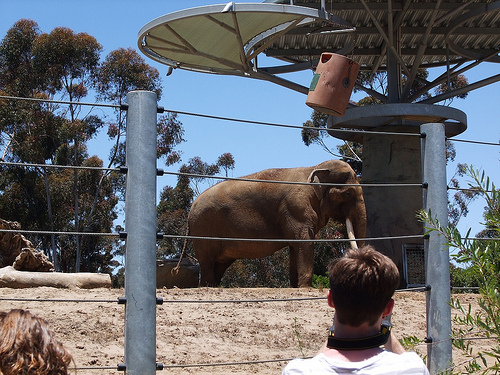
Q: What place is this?
A: It is a zoo.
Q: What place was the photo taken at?
A: It was taken at the zoo.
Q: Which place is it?
A: It is a zoo.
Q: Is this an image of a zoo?
A: Yes, it is showing a zoo.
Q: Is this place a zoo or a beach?
A: It is a zoo.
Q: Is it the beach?
A: No, it is the zoo.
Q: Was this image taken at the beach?
A: No, the picture was taken in the zoo.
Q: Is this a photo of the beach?
A: No, the picture is showing the zoo.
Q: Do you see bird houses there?
A: No, there are no bird houses.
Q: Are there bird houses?
A: No, there are no bird houses.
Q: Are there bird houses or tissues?
A: No, there are no bird houses or tissues.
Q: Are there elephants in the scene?
A: Yes, there is an elephant.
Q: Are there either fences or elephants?
A: Yes, there is an elephant.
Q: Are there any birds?
A: No, there are no birds.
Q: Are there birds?
A: No, there are no birds.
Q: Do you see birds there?
A: No, there are no birds.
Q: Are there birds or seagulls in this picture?
A: No, there are no birds or seagulls.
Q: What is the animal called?
A: The animal is an elephant.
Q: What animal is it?
A: The animal is an elephant.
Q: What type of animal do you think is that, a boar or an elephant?
A: This is an elephant.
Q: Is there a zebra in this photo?
A: No, there are no zebras.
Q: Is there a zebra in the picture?
A: No, there are no zebras.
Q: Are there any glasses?
A: No, there are no glasses.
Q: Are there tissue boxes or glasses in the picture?
A: No, there are no glasses or tissue boxes.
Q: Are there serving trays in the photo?
A: No, there are no serving trays.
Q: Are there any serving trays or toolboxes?
A: No, there are no serving trays or toolboxes.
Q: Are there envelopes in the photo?
A: No, there are no envelopes.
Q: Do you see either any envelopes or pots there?
A: No, there are no envelopes or pots.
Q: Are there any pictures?
A: No, there are no pictures.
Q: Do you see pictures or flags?
A: No, there are no pictures or flags.